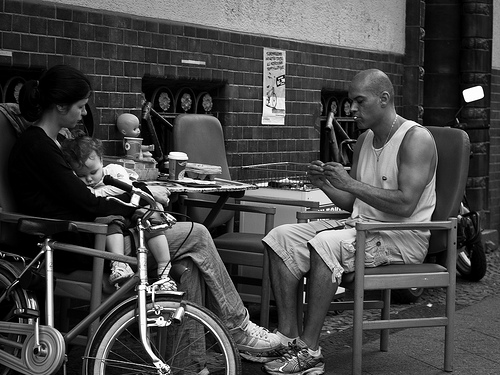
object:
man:
[236, 67, 438, 375]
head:
[347, 67, 396, 130]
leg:
[260, 225, 430, 375]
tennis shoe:
[259, 338, 327, 375]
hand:
[323, 161, 351, 189]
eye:
[357, 100, 363, 104]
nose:
[350, 102, 359, 114]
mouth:
[352, 114, 362, 123]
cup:
[167, 151, 189, 181]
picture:
[259, 47, 288, 126]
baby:
[58, 129, 178, 292]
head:
[18, 64, 94, 128]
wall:
[0, 0, 408, 188]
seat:
[0, 102, 171, 375]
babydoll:
[117, 112, 161, 164]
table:
[101, 172, 259, 354]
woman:
[2, 63, 281, 375]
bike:
[0, 174, 243, 375]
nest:
[2, 136, 173, 237]